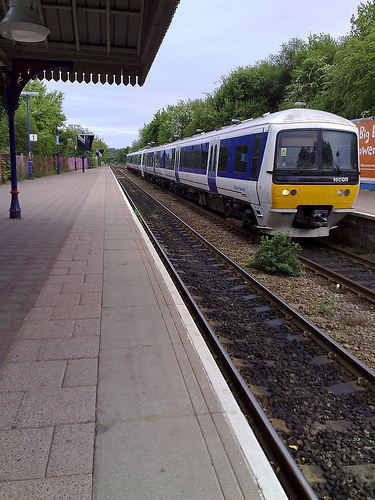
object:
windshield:
[271, 125, 363, 188]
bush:
[246, 230, 301, 276]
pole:
[26, 97, 33, 179]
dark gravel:
[115, 164, 375, 498]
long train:
[125, 102, 362, 241]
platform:
[0, 163, 277, 497]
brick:
[0, 233, 105, 498]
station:
[0, 26, 274, 500]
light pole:
[26, 93, 34, 180]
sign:
[347, 116, 375, 182]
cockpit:
[261, 107, 361, 232]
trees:
[0, 86, 88, 160]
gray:
[9, 368, 93, 473]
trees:
[131, 1, 375, 146]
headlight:
[281, 188, 291, 196]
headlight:
[337, 190, 344, 197]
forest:
[120, 2, 375, 148]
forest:
[0, 79, 117, 157]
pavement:
[0, 163, 268, 500]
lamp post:
[20, 91, 39, 180]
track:
[110, 162, 374, 499]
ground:
[2, 164, 375, 500]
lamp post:
[76, 130, 94, 173]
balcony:
[40, 165, 289, 498]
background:
[38, 77, 244, 164]